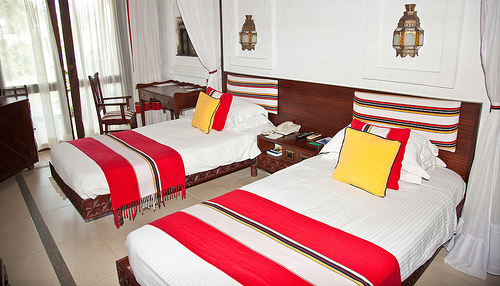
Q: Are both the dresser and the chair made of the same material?
A: Yes, both the dresser and the chair are made of wood.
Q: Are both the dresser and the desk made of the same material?
A: Yes, both the dresser and the desk are made of wood.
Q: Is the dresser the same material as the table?
A: Yes, both the dresser and the table are made of wood.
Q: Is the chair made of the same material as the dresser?
A: Yes, both the chair and the dresser are made of wood.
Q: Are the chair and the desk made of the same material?
A: Yes, both the chair and the desk are made of wood.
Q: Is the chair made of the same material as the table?
A: Yes, both the chair and the table are made of wood.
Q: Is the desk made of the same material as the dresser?
A: Yes, both the desk and the dresser are made of wood.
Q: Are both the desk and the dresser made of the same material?
A: Yes, both the desk and the dresser are made of wood.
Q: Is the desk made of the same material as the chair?
A: Yes, both the desk and the chair are made of wood.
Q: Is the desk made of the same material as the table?
A: Yes, both the desk and the table are made of wood.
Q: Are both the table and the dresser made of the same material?
A: Yes, both the table and the dresser are made of wood.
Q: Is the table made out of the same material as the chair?
A: Yes, both the table and the chair are made of wood.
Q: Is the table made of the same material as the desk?
A: Yes, both the table and the desk are made of wood.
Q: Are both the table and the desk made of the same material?
A: Yes, both the table and the desk are made of wood.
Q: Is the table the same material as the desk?
A: Yes, both the table and the desk are made of wood.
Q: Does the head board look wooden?
A: Yes, the head board is wooden.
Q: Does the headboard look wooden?
A: Yes, the headboard is wooden.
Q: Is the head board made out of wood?
A: Yes, the head board is made of wood.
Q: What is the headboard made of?
A: The head board is made of wood.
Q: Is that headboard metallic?
A: No, the headboard is wooden.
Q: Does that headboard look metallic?
A: No, the headboard is wooden.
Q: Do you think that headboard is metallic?
A: No, the headboard is wooden.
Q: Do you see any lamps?
A: Yes, there is a lamp.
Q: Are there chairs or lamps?
A: Yes, there is a lamp.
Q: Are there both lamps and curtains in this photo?
A: Yes, there are both a lamp and a curtain.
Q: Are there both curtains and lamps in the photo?
A: Yes, there are both a lamp and a curtain.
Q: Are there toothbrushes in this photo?
A: No, there are no toothbrushes.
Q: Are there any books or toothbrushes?
A: No, there are no toothbrushes or books.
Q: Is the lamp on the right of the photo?
A: Yes, the lamp is on the right of the image.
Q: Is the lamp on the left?
A: No, the lamp is on the right of the image.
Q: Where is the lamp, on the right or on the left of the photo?
A: The lamp is on the right of the image.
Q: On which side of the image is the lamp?
A: The lamp is on the right of the image.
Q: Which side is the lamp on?
A: The lamp is on the right of the image.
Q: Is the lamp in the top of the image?
A: Yes, the lamp is in the top of the image.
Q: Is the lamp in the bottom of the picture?
A: No, the lamp is in the top of the image.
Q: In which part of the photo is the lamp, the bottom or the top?
A: The lamp is in the top of the image.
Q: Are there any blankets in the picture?
A: Yes, there is a blanket.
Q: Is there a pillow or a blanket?
A: Yes, there is a blanket.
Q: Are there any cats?
A: No, there are no cats.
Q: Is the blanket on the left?
A: Yes, the blanket is on the left of the image.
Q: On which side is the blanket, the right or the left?
A: The blanket is on the left of the image.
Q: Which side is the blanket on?
A: The blanket is on the left of the image.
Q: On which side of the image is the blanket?
A: The blanket is on the left of the image.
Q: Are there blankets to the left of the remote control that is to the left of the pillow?
A: Yes, there is a blanket to the left of the remote control.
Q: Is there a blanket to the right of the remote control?
A: No, the blanket is to the left of the remote control.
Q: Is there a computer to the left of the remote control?
A: No, there is a blanket to the left of the remote control.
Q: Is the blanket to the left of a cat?
A: No, the blanket is to the left of a remote control.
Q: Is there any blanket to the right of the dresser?
A: Yes, there is a blanket to the right of the dresser.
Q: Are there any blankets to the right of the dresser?
A: Yes, there is a blanket to the right of the dresser.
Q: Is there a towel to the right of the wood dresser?
A: No, there is a blanket to the right of the dresser.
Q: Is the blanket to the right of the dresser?
A: Yes, the blanket is to the right of the dresser.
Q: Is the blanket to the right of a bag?
A: No, the blanket is to the right of the dresser.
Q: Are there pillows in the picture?
A: Yes, there is a pillow.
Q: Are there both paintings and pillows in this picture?
A: No, there is a pillow but no paintings.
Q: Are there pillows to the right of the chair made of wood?
A: Yes, there is a pillow to the right of the chair.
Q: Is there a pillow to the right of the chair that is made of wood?
A: Yes, there is a pillow to the right of the chair.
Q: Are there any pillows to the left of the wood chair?
A: No, the pillow is to the right of the chair.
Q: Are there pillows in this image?
A: Yes, there is a pillow.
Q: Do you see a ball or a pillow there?
A: Yes, there is a pillow.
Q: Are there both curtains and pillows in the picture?
A: Yes, there are both a pillow and a curtain.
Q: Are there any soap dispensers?
A: No, there are no soap dispensers.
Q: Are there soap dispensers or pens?
A: No, there are no soap dispensers or pens.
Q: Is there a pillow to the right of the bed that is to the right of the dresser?
A: Yes, there is a pillow to the right of the bed.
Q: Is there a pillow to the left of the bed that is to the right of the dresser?
A: No, the pillow is to the right of the bed.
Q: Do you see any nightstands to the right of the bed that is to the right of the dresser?
A: No, there is a pillow to the right of the bed.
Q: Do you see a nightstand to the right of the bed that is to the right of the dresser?
A: No, there is a pillow to the right of the bed.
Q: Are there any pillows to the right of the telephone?
A: Yes, there is a pillow to the right of the telephone.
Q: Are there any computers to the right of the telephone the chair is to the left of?
A: No, there is a pillow to the right of the phone.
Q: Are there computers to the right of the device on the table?
A: No, there is a pillow to the right of the phone.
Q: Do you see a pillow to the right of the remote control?
A: Yes, there is a pillow to the right of the remote control.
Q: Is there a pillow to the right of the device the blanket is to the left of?
A: Yes, there is a pillow to the right of the remote control.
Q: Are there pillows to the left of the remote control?
A: No, the pillow is to the right of the remote control.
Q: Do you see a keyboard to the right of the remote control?
A: No, there is a pillow to the right of the remote control.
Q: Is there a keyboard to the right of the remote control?
A: No, there is a pillow to the right of the remote control.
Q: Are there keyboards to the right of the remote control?
A: No, there is a pillow to the right of the remote control.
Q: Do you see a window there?
A: Yes, there is a window.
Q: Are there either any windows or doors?
A: Yes, there is a window.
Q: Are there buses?
A: No, there are no buses.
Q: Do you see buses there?
A: No, there are no buses.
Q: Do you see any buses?
A: No, there are no buses.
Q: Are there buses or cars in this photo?
A: No, there are no buses or cars.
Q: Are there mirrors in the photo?
A: No, there are no mirrors.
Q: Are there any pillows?
A: Yes, there is a pillow.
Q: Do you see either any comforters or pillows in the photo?
A: Yes, there is a pillow.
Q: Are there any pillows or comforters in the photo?
A: Yes, there is a pillow.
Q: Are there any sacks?
A: No, there are no sacks.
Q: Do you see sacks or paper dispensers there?
A: No, there are no sacks or paper dispensers.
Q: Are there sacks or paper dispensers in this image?
A: No, there are no sacks or paper dispensers.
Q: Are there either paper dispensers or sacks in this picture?
A: No, there are no sacks or paper dispensers.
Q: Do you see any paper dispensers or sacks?
A: No, there are no sacks or paper dispensers.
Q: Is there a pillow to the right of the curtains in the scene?
A: Yes, there is a pillow to the right of the curtains.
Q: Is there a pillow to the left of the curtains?
A: No, the pillow is to the right of the curtains.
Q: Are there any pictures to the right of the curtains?
A: No, there is a pillow to the right of the curtains.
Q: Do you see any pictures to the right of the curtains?
A: No, there is a pillow to the right of the curtains.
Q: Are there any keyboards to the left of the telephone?
A: No, there is a pillow to the left of the telephone.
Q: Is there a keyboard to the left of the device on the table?
A: No, there is a pillow to the left of the telephone.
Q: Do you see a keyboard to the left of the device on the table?
A: No, there is a pillow to the left of the telephone.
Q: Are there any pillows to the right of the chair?
A: Yes, there is a pillow to the right of the chair.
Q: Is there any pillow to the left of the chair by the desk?
A: No, the pillow is to the right of the chair.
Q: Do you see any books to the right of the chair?
A: No, there is a pillow to the right of the chair.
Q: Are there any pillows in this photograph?
A: Yes, there is a pillow.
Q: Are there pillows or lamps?
A: Yes, there is a pillow.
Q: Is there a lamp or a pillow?
A: Yes, there is a pillow.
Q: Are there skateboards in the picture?
A: No, there are no skateboards.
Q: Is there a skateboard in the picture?
A: No, there are no skateboards.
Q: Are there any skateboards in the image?
A: No, there are no skateboards.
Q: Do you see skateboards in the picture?
A: No, there are no skateboards.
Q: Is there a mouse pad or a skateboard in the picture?
A: No, there are no skateboards or mouse pads.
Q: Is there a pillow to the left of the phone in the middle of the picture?
A: Yes, there is a pillow to the left of the phone.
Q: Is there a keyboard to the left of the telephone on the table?
A: No, there is a pillow to the left of the telephone.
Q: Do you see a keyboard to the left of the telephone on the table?
A: No, there is a pillow to the left of the telephone.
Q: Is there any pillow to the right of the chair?
A: Yes, there is a pillow to the right of the chair.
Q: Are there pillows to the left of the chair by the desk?
A: No, the pillow is to the right of the chair.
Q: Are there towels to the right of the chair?
A: No, there is a pillow to the right of the chair.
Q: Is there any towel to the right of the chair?
A: No, there is a pillow to the right of the chair.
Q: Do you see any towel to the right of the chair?
A: No, there is a pillow to the right of the chair.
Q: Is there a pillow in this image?
A: Yes, there is a pillow.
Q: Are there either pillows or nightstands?
A: Yes, there is a pillow.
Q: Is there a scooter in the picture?
A: No, there are no scooters.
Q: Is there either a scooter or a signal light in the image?
A: No, there are no scooters or traffic lights.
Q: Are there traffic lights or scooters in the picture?
A: No, there are no scooters or traffic lights.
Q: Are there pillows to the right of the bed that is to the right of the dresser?
A: Yes, there is a pillow to the right of the bed.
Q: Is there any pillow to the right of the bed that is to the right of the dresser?
A: Yes, there is a pillow to the right of the bed.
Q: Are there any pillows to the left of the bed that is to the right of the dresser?
A: No, the pillow is to the right of the bed.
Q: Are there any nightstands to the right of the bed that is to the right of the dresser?
A: No, there is a pillow to the right of the bed.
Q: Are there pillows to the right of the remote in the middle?
A: Yes, there is a pillow to the right of the remote control.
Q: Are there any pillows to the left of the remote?
A: No, the pillow is to the right of the remote.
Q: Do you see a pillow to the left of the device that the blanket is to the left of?
A: No, the pillow is to the right of the remote.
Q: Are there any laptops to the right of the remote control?
A: No, there is a pillow to the right of the remote control.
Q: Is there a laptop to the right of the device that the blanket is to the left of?
A: No, there is a pillow to the right of the remote control.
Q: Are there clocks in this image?
A: No, there are no clocks.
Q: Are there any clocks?
A: No, there are no clocks.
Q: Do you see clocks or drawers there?
A: No, there are no clocks or drawers.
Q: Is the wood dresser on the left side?
A: Yes, the dresser is on the left of the image.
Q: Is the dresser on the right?
A: No, the dresser is on the left of the image.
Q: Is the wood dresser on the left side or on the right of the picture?
A: The dresser is on the left of the image.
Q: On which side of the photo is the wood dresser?
A: The dresser is on the left of the image.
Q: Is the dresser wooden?
A: Yes, the dresser is wooden.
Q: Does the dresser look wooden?
A: Yes, the dresser is wooden.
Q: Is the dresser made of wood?
A: Yes, the dresser is made of wood.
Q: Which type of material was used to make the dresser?
A: The dresser is made of wood.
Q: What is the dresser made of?
A: The dresser is made of wood.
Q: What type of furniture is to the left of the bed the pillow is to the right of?
A: The piece of furniture is a dresser.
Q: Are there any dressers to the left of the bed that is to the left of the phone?
A: Yes, there is a dresser to the left of the bed.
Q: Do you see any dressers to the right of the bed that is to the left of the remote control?
A: No, the dresser is to the left of the bed.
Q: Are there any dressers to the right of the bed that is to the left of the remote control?
A: No, the dresser is to the left of the bed.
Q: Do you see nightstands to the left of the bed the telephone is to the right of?
A: No, there is a dresser to the left of the bed.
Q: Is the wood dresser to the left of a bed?
A: Yes, the dresser is to the left of a bed.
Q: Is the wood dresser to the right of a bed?
A: No, the dresser is to the left of a bed.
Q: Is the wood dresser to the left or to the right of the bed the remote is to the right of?
A: The dresser is to the left of the bed.